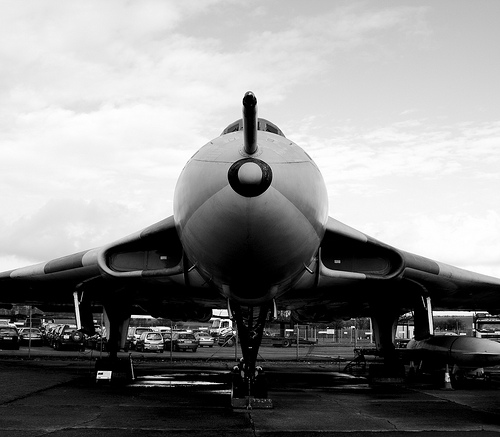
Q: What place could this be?
A: It is an airport.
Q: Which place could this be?
A: It is an airport.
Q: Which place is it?
A: It is an airport.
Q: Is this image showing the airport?
A: Yes, it is showing the airport.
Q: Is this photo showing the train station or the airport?
A: It is showing the airport.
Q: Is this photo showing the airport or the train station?
A: It is showing the airport.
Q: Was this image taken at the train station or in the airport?
A: It was taken at the airport.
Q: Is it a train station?
A: No, it is an airport.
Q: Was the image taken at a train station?
A: No, the picture was taken in an airport.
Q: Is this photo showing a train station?
A: No, the picture is showing an airport.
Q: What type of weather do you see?
A: It is clear.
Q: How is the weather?
A: It is clear.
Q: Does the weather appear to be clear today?
A: Yes, it is clear.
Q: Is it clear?
A: Yes, it is clear.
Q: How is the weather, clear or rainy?
A: It is clear.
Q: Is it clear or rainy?
A: It is clear.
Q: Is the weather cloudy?
A: No, it is clear.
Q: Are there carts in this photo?
A: No, there are no carts.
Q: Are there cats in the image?
A: No, there are no cats.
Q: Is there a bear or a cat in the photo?
A: No, there are no cats or bears.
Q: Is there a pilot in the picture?
A: No, there are no pilots.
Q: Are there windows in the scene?
A: Yes, there are windows.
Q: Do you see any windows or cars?
A: Yes, there are windows.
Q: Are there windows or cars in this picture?
A: Yes, there are windows.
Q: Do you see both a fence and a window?
A: Yes, there are both a window and a fence.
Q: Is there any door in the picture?
A: No, there are no doors.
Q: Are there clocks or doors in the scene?
A: No, there are no doors or clocks.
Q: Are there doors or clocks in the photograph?
A: No, there are no doors or clocks.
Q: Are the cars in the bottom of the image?
A: Yes, the cars are in the bottom of the image.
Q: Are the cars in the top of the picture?
A: No, the cars are in the bottom of the image.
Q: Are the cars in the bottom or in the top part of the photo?
A: The cars are in the bottom of the image.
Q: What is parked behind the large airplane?
A: The cars are parked behind the plane.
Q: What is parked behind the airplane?
A: The cars are parked behind the plane.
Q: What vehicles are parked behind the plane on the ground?
A: The vehicles are cars.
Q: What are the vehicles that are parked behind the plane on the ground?
A: The vehicles are cars.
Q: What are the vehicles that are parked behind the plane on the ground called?
A: The vehicles are cars.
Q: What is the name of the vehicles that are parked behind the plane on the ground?
A: The vehicles are cars.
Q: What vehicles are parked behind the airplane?
A: The vehicles are cars.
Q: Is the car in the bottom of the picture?
A: Yes, the car is in the bottom of the image.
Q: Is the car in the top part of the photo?
A: No, the car is in the bottom of the image.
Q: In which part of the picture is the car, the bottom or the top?
A: The car is in the bottom of the image.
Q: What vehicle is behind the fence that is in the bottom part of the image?
A: The vehicle is a car.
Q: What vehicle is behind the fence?
A: The vehicle is a car.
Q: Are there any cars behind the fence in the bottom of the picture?
A: Yes, there is a car behind the fence.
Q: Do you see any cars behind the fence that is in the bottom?
A: Yes, there is a car behind the fence.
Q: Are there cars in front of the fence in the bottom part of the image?
A: No, the car is behind the fence.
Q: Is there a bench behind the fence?
A: No, there is a car behind the fence.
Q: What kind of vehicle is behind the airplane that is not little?
A: The vehicle is a car.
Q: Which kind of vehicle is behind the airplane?
A: The vehicle is a car.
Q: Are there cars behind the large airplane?
A: Yes, there is a car behind the plane.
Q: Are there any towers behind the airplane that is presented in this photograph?
A: No, there is a car behind the airplane.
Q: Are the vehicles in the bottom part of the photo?
A: Yes, the vehicles are in the bottom of the image.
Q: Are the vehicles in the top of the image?
A: No, the vehicles are in the bottom of the image.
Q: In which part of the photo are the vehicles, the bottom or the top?
A: The vehicles are in the bottom of the image.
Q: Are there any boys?
A: No, there are no boys.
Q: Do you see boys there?
A: No, there are no boys.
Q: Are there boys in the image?
A: No, there are no boys.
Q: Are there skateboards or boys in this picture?
A: No, there are no boys or skateboards.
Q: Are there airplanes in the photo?
A: Yes, there is an airplane.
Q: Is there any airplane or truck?
A: Yes, there is an airplane.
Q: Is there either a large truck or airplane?
A: Yes, there is a large airplane.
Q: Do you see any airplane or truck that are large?
A: Yes, the airplane is large.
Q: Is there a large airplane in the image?
A: Yes, there is a large airplane.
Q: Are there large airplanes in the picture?
A: Yes, there is a large airplane.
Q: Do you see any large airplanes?
A: Yes, there is a large airplane.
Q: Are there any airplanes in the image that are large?
A: Yes, there is a large airplane.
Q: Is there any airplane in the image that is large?
A: Yes, there is an airplane that is large.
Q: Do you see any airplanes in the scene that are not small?
A: Yes, there is a large airplane.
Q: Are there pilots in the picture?
A: No, there are no pilots.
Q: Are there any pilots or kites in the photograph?
A: No, there are no pilots or kites.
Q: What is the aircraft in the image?
A: The aircraft is an airplane.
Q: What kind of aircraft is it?
A: The aircraft is an airplane.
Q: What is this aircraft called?
A: This is an airplane.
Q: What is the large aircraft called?
A: The aircraft is an airplane.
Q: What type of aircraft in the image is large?
A: The aircraft is an airplane.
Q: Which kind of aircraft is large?
A: The aircraft is an airplane.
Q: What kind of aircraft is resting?
A: The aircraft is an airplane.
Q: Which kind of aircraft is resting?
A: The aircraft is an airplane.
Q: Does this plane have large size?
A: Yes, the plane is large.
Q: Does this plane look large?
A: Yes, the plane is large.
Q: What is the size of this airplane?
A: The airplane is large.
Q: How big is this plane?
A: The plane is large.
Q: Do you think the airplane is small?
A: No, the airplane is large.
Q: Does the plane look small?
A: No, the plane is large.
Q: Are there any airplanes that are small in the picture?
A: No, there is an airplane but it is large.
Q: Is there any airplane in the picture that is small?
A: No, there is an airplane but it is large.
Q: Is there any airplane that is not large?
A: No, there is an airplane but it is large.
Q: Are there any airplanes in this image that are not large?
A: No, there is an airplane but it is large.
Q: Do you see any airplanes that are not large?
A: No, there is an airplane but it is large.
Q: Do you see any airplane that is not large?
A: No, there is an airplane but it is large.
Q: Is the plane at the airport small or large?
A: The plane is large.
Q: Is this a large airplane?
A: Yes, this is a large airplane.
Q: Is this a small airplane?
A: No, this is a large airplane.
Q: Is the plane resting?
A: Yes, the plane is resting.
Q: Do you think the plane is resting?
A: Yes, the plane is resting.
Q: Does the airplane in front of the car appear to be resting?
A: Yes, the plane is resting.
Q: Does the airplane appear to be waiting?
A: No, the airplane is resting.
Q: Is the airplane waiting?
A: No, the airplane is resting.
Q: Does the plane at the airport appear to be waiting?
A: No, the plane is resting.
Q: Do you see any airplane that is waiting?
A: No, there is an airplane but it is resting.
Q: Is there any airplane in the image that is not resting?
A: No, there is an airplane but it is resting.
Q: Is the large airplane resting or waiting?
A: The airplane is resting.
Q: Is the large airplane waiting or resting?
A: The airplane is resting.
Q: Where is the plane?
A: The plane is at the airport.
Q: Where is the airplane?
A: The plane is at the airport.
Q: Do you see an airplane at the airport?
A: Yes, there is an airplane at the airport.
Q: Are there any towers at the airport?
A: No, there is an airplane at the airport.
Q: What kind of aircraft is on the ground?
A: The aircraft is an airplane.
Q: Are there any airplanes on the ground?
A: Yes, there is an airplane on the ground.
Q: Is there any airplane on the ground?
A: Yes, there is an airplane on the ground.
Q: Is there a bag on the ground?
A: No, there is an airplane on the ground.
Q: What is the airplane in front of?
A: The airplane is in front of the car.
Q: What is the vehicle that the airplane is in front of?
A: The vehicle is a car.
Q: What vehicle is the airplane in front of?
A: The airplane is in front of the car.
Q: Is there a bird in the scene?
A: No, there are no birds.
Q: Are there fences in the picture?
A: Yes, there is a fence.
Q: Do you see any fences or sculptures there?
A: Yes, there is a fence.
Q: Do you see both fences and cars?
A: Yes, there are both a fence and a car.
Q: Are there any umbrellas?
A: No, there are no umbrellas.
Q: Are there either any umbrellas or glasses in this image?
A: No, there are no umbrellas or glasses.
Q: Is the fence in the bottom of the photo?
A: Yes, the fence is in the bottom of the image.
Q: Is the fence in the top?
A: No, the fence is in the bottom of the image.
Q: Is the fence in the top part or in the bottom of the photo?
A: The fence is in the bottom of the image.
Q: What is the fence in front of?
A: The fence is in front of the car.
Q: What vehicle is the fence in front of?
A: The fence is in front of the car.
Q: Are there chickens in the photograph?
A: No, there are no chickens.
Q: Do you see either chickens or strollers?
A: No, there are no chickens or strollers.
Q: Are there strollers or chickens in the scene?
A: No, there are no chickens or strollers.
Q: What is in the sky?
A: The clouds are in the sky.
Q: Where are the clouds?
A: The clouds are in the sky.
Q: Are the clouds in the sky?
A: Yes, the clouds are in the sky.